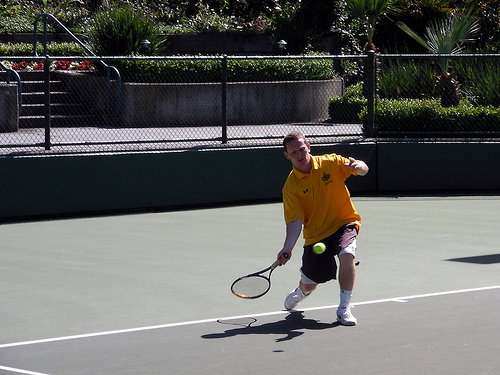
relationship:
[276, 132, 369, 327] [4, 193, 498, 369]
man on a tennis court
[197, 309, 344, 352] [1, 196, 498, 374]
shadow on ground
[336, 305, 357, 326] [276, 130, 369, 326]
shoe of man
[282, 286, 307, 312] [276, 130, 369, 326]
shoe of man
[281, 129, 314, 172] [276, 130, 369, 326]
head of man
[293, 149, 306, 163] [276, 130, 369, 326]
nose of man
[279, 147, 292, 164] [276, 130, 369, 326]
ear of man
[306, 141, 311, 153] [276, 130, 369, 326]
ear of man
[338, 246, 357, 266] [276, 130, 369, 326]
knee of man